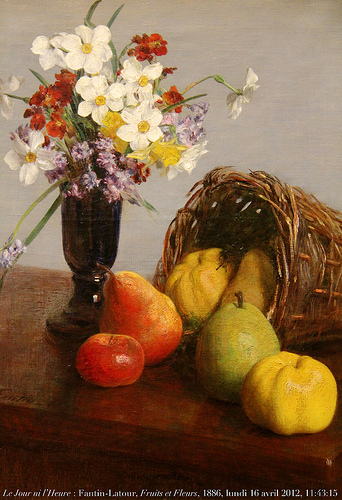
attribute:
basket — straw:
[153, 164, 340, 345]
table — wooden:
[0, 260, 341, 498]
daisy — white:
[119, 100, 162, 148]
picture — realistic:
[7, 14, 290, 253]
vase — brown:
[44, 177, 132, 347]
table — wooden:
[3, 265, 340, 446]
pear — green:
[194, 290, 281, 403]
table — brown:
[0, 341, 89, 422]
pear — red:
[75, 265, 176, 358]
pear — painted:
[95, 277, 199, 381]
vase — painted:
[46, 161, 131, 342]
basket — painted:
[147, 147, 336, 360]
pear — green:
[186, 279, 271, 403]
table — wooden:
[57, 375, 217, 495]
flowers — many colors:
[2, 25, 258, 263]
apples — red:
[66, 262, 302, 385]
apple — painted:
[76, 309, 188, 406]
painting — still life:
[7, 5, 332, 481]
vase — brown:
[31, 166, 149, 343]